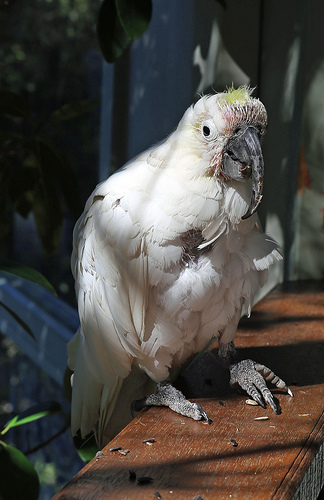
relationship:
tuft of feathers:
[218, 81, 257, 104] [196, 68, 275, 175]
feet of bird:
[125, 341, 293, 431] [66, 89, 286, 392]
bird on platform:
[63, 79, 294, 451] [49, 279, 323, 499]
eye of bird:
[207, 119, 220, 143] [77, 67, 294, 423]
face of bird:
[186, 85, 284, 219] [37, 88, 298, 343]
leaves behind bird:
[1, 0, 155, 256] [63, 79, 294, 451]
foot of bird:
[215, 348, 298, 415] [73, 85, 274, 336]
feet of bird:
[142, 367, 214, 431] [73, 85, 274, 336]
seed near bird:
[216, 399, 228, 406] [49, 70, 299, 437]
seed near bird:
[254, 414, 267, 420] [63, 79, 294, 451]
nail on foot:
[265, 392, 285, 414] [211, 330, 292, 417]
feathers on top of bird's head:
[217, 82, 250, 108] [163, 74, 292, 225]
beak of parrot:
[237, 127, 265, 218] [72, 23, 302, 419]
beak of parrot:
[225, 127, 258, 189] [55, 81, 299, 454]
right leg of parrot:
[162, 399, 193, 450] [87, 299, 261, 481]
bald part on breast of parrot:
[160, 259, 210, 310] [55, 81, 299, 454]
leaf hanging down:
[113, 0, 153, 39] [9, 378, 40, 474]